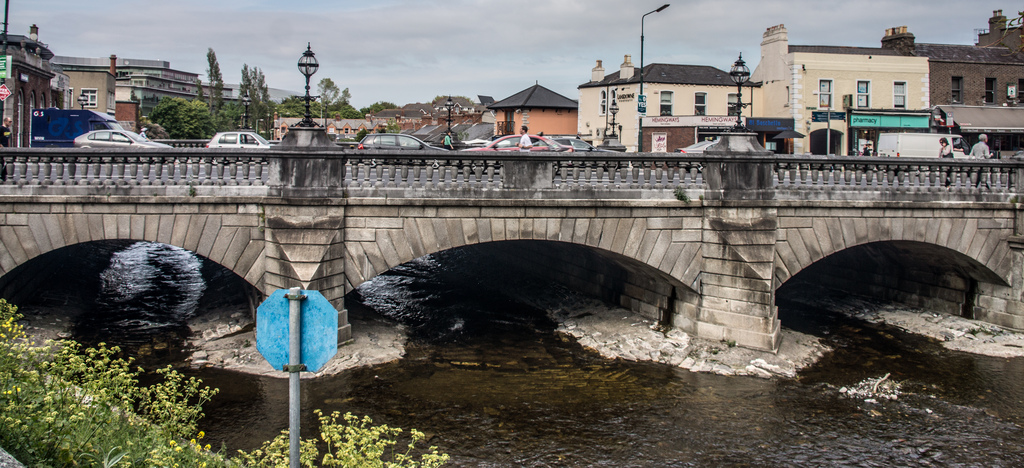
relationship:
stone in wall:
[506, 215, 522, 242] [336, 150, 741, 347]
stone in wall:
[526, 209, 553, 233] [342, 170, 708, 318]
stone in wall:
[558, 209, 576, 251] [345, 202, 709, 339]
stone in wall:
[563, 215, 581, 246] [347, 206, 698, 299]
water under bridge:
[12, 237, 1000, 466] [6, 145, 1020, 362]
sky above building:
[1, 1, 1023, 110] [576, 36, 933, 160]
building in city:
[487, 59, 911, 185] [2, 46, 918, 256]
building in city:
[602, 48, 782, 154] [53, 50, 892, 262]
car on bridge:
[69, 121, 162, 169] [2, 136, 1018, 404]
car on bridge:
[359, 133, 440, 181] [2, 88, 1018, 367]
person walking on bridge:
[9, 140, 1021, 370] [505, 114, 553, 166]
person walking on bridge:
[966, 121, 999, 165] [2, 136, 1018, 404]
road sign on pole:
[252, 284, 339, 380] [285, 300, 322, 456]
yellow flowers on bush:
[40, 335, 196, 454] [17, 320, 260, 463]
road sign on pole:
[252, 268, 346, 443] [281, 286, 310, 468]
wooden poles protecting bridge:
[341, 145, 529, 202] [2, 136, 1018, 404]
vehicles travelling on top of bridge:
[41, 108, 830, 175] [6, 145, 1020, 362]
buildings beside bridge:
[565, 13, 982, 156] [6, 145, 1020, 362]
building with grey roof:
[479, 80, 613, 141] [481, 78, 568, 122]